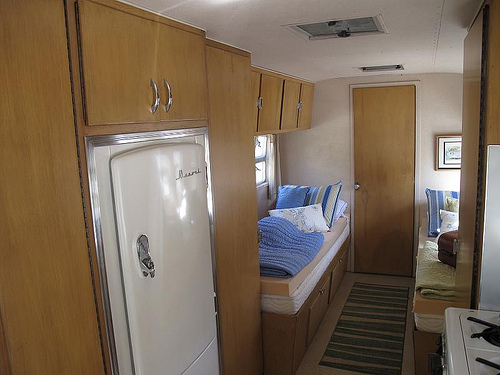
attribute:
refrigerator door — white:
[111, 145, 229, 367]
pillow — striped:
[294, 180, 338, 220]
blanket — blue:
[262, 210, 317, 278]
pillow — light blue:
[276, 183, 310, 220]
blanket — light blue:
[256, 216, 314, 283]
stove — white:
[459, 306, 499, 348]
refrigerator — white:
[102, 134, 238, 371]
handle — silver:
[148, 74, 164, 112]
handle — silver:
[162, 76, 176, 109]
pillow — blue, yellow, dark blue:
[301, 182, 343, 226]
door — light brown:
[350, 82, 415, 283]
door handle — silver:
[347, 175, 366, 194]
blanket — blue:
[252, 213, 325, 278]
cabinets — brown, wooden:
[249, 60, 320, 136]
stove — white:
[434, 301, 495, 372]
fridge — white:
[86, 119, 233, 372]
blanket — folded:
[413, 232, 457, 303]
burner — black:
[464, 310, 497, 347]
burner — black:
[476, 353, 497, 371]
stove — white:
[436, 299, 499, 372]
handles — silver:
[146, 76, 163, 116]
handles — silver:
[159, 70, 179, 112]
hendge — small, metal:
[146, 76, 166, 114]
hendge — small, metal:
[158, 74, 176, 114]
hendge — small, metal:
[252, 91, 268, 113]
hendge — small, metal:
[292, 94, 307, 118]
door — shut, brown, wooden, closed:
[345, 78, 425, 283]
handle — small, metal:
[347, 174, 363, 192]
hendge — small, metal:
[316, 281, 328, 300]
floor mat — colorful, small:
[318, 280, 411, 371]